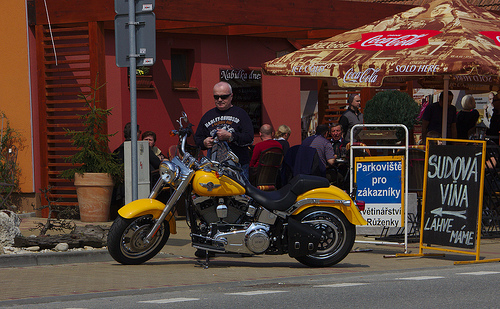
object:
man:
[190, 82, 253, 258]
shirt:
[192, 105, 255, 165]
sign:
[382, 136, 500, 268]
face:
[211, 82, 233, 108]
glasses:
[213, 92, 233, 100]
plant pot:
[73, 171, 115, 223]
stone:
[52, 241, 69, 253]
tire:
[289, 202, 356, 268]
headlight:
[158, 159, 178, 184]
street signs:
[348, 125, 413, 256]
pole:
[124, 0, 141, 201]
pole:
[438, 70, 448, 145]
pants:
[188, 161, 253, 197]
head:
[211, 82, 233, 109]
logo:
[340, 66, 381, 83]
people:
[251, 123, 351, 180]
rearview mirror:
[225, 149, 239, 163]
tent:
[262, 0, 499, 89]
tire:
[106, 208, 168, 266]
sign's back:
[113, 1, 157, 68]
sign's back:
[122, 140, 152, 204]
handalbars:
[172, 110, 252, 168]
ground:
[0, 219, 500, 308]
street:
[0, 246, 499, 308]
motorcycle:
[108, 110, 368, 268]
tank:
[193, 167, 243, 197]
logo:
[348, 25, 444, 51]